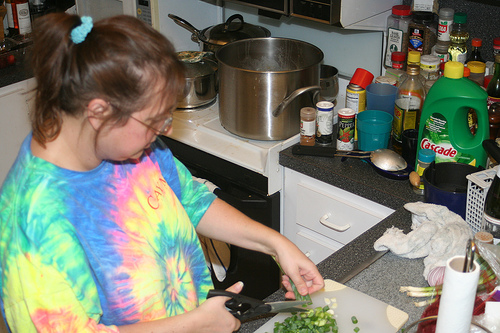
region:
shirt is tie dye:
[1, 133, 219, 332]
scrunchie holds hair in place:
[70, 10, 92, 42]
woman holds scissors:
[0, 12, 326, 332]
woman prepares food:
[0, 11, 323, 332]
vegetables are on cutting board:
[272, 290, 363, 332]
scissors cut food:
[205, 287, 310, 322]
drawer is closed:
[282, 169, 385, 246]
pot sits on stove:
[216, 35, 326, 144]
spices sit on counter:
[297, 97, 357, 152]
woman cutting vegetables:
[2, 10, 322, 330]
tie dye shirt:
[4, 133, 213, 331]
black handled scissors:
[205, 285, 315, 323]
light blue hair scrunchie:
[70, 12, 92, 43]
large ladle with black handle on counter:
[290, 136, 407, 171]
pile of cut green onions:
[270, 300, 357, 332]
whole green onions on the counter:
[398, 259, 494, 304]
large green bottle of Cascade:
[413, 60, 481, 170]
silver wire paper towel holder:
[396, 238, 486, 331]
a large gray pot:
[220, 32, 326, 138]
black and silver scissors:
[201, 285, 308, 322]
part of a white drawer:
[292, 185, 379, 240]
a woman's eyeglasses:
[122, 109, 176, 136]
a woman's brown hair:
[36, 11, 184, 158]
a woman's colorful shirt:
[0, 139, 215, 331]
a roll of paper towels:
[438, 253, 483, 330]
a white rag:
[372, 196, 468, 263]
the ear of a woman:
[84, 98, 111, 132]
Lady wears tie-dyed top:
[1, 128, 218, 332]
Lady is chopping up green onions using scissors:
[195, 250, 362, 330]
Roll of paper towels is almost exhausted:
[432, 234, 486, 331]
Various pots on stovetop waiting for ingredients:
[154, 8, 344, 158]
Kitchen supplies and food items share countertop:
[294, 0, 499, 202]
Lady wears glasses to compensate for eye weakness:
[96, 64, 195, 184]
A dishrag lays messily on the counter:
[372, 193, 494, 291]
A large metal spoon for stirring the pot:
[286, 138, 408, 179]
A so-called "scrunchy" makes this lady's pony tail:
[23, 6, 102, 158]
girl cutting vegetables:
[15, 35, 321, 330]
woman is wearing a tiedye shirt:
[0, 107, 321, 329]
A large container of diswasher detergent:
[411, 58, 487, 179]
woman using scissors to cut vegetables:
[200, 285, 316, 327]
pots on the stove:
[151, 16, 339, 146]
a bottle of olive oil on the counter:
[397, 66, 417, 151]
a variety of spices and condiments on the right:
[373, 5, 488, 93]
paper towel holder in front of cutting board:
[400, 240, 481, 328]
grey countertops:
[239, 112, 484, 329]